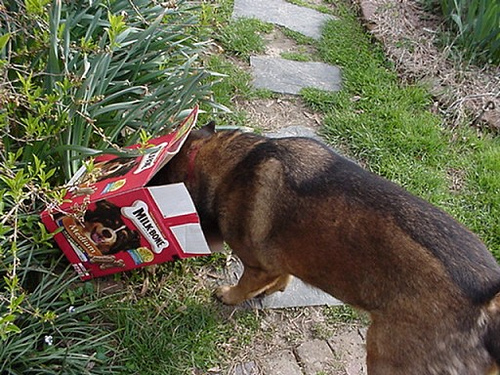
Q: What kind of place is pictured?
A: It is a path.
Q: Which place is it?
A: It is a path.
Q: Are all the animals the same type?
A: Yes, all the animals are dogs.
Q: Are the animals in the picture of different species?
A: No, all the animals are dogs.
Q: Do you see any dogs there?
A: Yes, there is a dog.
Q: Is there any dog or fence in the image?
A: Yes, there is a dog.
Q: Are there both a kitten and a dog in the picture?
A: No, there is a dog but no kittens.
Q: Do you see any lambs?
A: No, there are no lambs.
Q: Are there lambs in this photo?
A: No, there are no lambs.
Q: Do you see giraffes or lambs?
A: No, there are no lambs or giraffes.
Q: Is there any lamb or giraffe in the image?
A: No, there are no lambs or giraffes.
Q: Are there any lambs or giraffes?
A: No, there are no lambs or giraffes.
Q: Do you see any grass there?
A: Yes, there is grass.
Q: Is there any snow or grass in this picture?
A: Yes, there is grass.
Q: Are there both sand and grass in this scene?
A: No, there is grass but no sand.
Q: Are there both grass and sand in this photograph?
A: No, there is grass but no sand.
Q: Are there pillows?
A: No, there are no pillows.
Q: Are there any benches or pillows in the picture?
A: No, there are no pillows or benches.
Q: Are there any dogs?
A: Yes, there is a dog.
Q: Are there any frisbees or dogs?
A: Yes, there is a dog.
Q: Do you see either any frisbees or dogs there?
A: Yes, there is a dog.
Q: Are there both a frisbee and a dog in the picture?
A: No, there is a dog but no frisbees.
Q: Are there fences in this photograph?
A: No, there are no fences.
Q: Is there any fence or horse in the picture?
A: No, there are no fences or horses.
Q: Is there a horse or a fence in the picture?
A: No, there are no fences or horses.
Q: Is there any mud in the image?
A: Yes, there is mud.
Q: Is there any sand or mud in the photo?
A: Yes, there is mud.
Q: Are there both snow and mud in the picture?
A: No, there is mud but no snow.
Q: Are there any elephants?
A: No, there are no elephants.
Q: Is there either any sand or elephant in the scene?
A: No, there are no elephants or sand.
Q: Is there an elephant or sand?
A: No, there are no elephants or sand.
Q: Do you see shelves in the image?
A: No, there are no shelves.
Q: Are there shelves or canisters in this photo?
A: No, there are no shelves or canisters.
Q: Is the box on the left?
A: Yes, the box is on the left of the image.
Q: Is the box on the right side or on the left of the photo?
A: The box is on the left of the image.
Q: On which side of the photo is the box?
A: The box is on the left of the image.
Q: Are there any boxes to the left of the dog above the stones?
A: Yes, there is a box to the left of the dog.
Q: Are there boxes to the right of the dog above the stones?
A: No, the box is to the left of the dog.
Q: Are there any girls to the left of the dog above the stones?
A: No, there is a box to the left of the dog.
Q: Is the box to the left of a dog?
A: Yes, the box is to the left of a dog.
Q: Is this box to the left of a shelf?
A: No, the box is to the left of a dog.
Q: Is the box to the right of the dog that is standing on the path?
A: No, the box is to the left of the dog.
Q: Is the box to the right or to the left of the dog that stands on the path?
A: The box is to the left of the dog.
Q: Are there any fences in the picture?
A: No, there are no fences.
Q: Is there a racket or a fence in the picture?
A: No, there are no fences or rackets.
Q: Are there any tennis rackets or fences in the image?
A: No, there are no fences or tennis rackets.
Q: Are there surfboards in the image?
A: No, there are no surfboards.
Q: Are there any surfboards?
A: No, there are no surfboards.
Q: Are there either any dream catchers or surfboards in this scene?
A: No, there are no surfboards or dream catchers.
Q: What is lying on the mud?
A: The stones are lying on the mud.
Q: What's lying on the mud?
A: The stones are lying on the mud.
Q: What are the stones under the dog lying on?
A: The stones are lying on the mud.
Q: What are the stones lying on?
A: The stones are lying on the mud.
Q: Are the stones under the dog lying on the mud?
A: Yes, the stones are lying on the mud.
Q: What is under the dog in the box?
A: The stones are under the dog.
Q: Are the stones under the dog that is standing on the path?
A: Yes, the stones are under the dog.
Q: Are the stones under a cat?
A: No, the stones are under the dog.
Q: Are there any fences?
A: No, there are no fences.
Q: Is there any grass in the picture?
A: Yes, there is grass.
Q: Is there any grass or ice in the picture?
A: Yes, there is grass.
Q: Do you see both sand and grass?
A: No, there is grass but no sand.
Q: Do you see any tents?
A: No, there are no tents.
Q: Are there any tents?
A: No, there are no tents.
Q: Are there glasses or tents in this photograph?
A: No, there are no tents or glasses.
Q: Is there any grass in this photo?
A: Yes, there is grass.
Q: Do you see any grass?
A: Yes, there is grass.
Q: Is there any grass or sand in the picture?
A: Yes, there is grass.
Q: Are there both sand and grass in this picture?
A: No, there is grass but no sand.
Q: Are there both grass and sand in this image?
A: No, there is grass but no sand.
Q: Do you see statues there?
A: No, there are no statues.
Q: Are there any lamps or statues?
A: No, there are no statues or lamps.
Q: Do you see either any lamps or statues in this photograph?
A: No, there are no statues or lamps.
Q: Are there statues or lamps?
A: No, there are no statues or lamps.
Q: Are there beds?
A: No, there are no beds.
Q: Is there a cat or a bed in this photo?
A: No, there are no beds or cats.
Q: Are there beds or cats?
A: No, there are no beds or cats.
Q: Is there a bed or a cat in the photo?
A: No, there are no beds or cats.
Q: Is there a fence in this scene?
A: No, there are no fences.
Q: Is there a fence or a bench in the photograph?
A: No, there are no fences or benches.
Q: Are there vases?
A: No, there are no vases.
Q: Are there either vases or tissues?
A: No, there are no vases or tissues.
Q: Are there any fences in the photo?
A: No, there are no fences.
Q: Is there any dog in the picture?
A: Yes, there is a dog.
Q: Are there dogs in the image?
A: Yes, there is a dog.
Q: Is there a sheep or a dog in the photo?
A: Yes, there is a dog.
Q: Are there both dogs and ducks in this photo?
A: No, there is a dog but no ducks.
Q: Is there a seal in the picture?
A: No, there are no seals.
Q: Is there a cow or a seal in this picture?
A: No, there are no seals or cows.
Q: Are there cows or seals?
A: No, there are no seals or cows.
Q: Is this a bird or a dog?
A: This is a dog.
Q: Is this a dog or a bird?
A: This is a dog.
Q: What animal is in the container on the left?
A: The dog is in the box.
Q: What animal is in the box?
A: The dog is in the box.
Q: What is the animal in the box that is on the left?
A: The animal is a dog.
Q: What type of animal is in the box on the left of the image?
A: The animal is a dog.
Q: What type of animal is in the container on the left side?
A: The animal is a dog.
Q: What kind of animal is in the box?
A: The animal is a dog.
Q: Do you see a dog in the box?
A: Yes, there is a dog in the box.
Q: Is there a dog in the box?
A: Yes, there is a dog in the box.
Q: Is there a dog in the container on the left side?
A: Yes, there is a dog in the box.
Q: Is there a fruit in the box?
A: No, there is a dog in the box.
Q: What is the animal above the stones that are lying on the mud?
A: The animal is a dog.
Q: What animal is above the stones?
A: The animal is a dog.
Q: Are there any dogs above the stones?
A: Yes, there is a dog above the stones.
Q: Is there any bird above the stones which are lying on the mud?
A: No, there is a dog above the stones.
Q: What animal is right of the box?
A: The animal is a dog.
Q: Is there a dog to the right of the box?
A: Yes, there is a dog to the right of the box.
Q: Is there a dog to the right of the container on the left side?
A: Yes, there is a dog to the right of the box.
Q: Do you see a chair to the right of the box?
A: No, there is a dog to the right of the box.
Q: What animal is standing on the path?
A: The dog is standing on the path.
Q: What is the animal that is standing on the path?
A: The animal is a dog.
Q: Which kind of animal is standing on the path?
A: The animal is a dog.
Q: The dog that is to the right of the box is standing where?
A: The dog is standing on the path.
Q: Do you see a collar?
A: Yes, there is a collar.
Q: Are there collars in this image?
A: Yes, there is a collar.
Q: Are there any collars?
A: Yes, there is a collar.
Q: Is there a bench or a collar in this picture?
A: Yes, there is a collar.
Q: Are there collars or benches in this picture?
A: Yes, there is a collar.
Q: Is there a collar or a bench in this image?
A: Yes, there is a collar.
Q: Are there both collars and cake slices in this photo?
A: No, there is a collar but no cake slices.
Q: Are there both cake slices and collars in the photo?
A: No, there is a collar but no cake slices.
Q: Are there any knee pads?
A: No, there are no knee pads.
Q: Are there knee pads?
A: No, there are no knee pads.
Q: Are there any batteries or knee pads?
A: No, there are no knee pads or batteries.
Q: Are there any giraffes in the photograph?
A: No, there are no giraffes.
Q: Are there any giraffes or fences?
A: No, there are no giraffes or fences.